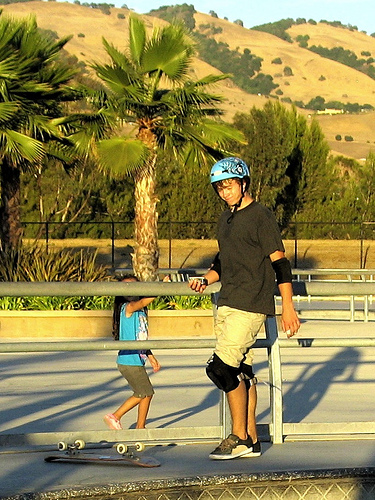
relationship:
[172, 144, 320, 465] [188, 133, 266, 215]
boy wearing a blue helmet helmet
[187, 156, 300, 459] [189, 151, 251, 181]
boy wearing helmet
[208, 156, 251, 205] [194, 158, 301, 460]
head of boy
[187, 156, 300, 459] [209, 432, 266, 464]
boy wearing shoes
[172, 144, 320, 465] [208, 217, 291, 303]
boy wearing shirt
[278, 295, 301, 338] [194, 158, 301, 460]
hand of boy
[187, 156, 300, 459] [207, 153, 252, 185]
boy wearing helmet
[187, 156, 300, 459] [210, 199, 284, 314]
boy wearing gray shirt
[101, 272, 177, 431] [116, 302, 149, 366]
girl wearing shirt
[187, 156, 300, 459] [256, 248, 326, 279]
boy wearing pads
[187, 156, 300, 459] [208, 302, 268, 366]
boy wearing shorts